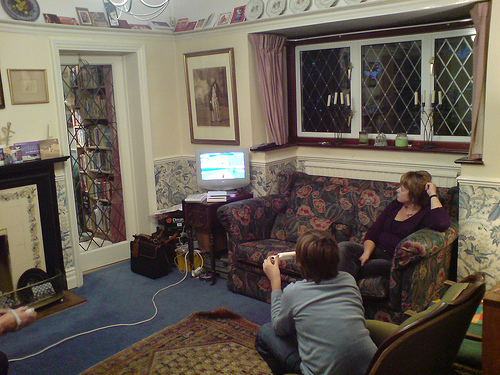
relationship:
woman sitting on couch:
[338, 171, 452, 284] [215, 169, 461, 320]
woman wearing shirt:
[338, 171, 452, 284] [364, 197, 446, 253]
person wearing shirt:
[263, 230, 384, 375] [270, 275, 386, 374]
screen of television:
[201, 153, 244, 179] [195, 150, 250, 190]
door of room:
[56, 51, 148, 264] [1, 0, 500, 374]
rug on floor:
[77, 309, 271, 374] [4, 259, 268, 374]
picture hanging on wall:
[182, 49, 240, 145] [1, 22, 252, 268]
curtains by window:
[248, 32, 292, 144] [288, 29, 480, 147]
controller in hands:
[269, 249, 304, 262] [262, 259, 285, 292]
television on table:
[195, 150, 250, 190] [179, 194, 247, 279]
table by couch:
[179, 194, 247, 279] [215, 169, 461, 320]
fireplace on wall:
[0, 168, 64, 304] [1, 22, 252, 268]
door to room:
[56, 51, 148, 264] [1, 0, 500, 374]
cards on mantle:
[0, 139, 59, 161] [0, 154, 71, 174]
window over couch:
[288, 29, 480, 147] [215, 169, 461, 320]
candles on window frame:
[322, 91, 446, 144] [291, 128, 474, 155]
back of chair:
[384, 295, 486, 374] [340, 268, 484, 374]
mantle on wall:
[0, 154, 71, 174] [1, 22, 252, 268]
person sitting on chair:
[263, 230, 384, 375] [340, 268, 484, 374]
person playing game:
[263, 230, 384, 375] [193, 150, 252, 201]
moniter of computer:
[201, 153, 244, 179] [195, 150, 250, 190]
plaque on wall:
[7, 67, 49, 105] [1, 22, 252, 268]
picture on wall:
[182, 49, 240, 145] [1, 22, 252, 268]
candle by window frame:
[358, 128, 369, 142] [291, 128, 474, 155]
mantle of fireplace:
[0, 154, 71, 174] [0, 168, 64, 304]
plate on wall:
[7, 0, 40, 23] [1, 22, 252, 268]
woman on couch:
[338, 171, 452, 284] [215, 169, 461, 320]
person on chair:
[263, 230, 384, 375] [340, 268, 484, 374]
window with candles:
[288, 29, 480, 147] [322, 91, 446, 144]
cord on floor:
[9, 246, 203, 369] [4, 259, 268, 374]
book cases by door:
[74, 69, 127, 242] [56, 51, 148, 264]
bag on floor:
[129, 235, 172, 278] [4, 259, 268, 374]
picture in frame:
[182, 49, 240, 145] [184, 52, 241, 146]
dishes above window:
[243, 0, 353, 25] [288, 29, 480, 147]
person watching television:
[263, 230, 384, 375] [195, 150, 250, 190]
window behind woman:
[288, 29, 480, 147] [338, 171, 452, 284]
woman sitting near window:
[338, 171, 452, 284] [288, 29, 480, 147]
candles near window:
[322, 91, 446, 144] [288, 29, 480, 147]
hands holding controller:
[262, 259, 285, 292] [269, 249, 304, 262]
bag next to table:
[129, 235, 172, 278] [179, 194, 247, 279]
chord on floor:
[4, 259, 268, 374] [4, 259, 268, 374]